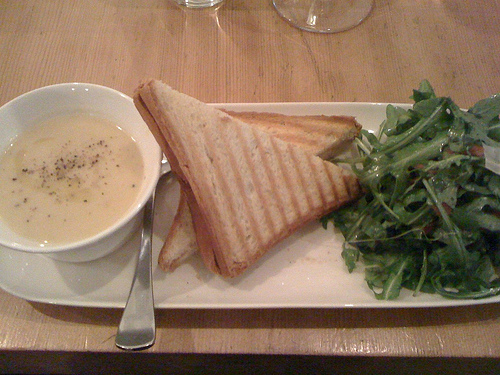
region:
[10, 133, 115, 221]
sprinkled black pepper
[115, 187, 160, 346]
handle of silver piece of silverware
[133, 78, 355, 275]
toasted half of sandwich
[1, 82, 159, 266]
cream soup in white bowl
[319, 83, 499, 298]
green leafy salad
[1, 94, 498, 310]
narrow white ceramic plate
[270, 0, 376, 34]
base of a clear glass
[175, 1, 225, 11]
base of a clear glass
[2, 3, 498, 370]
smooth flat wooden table top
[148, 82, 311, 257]
white and tan pieces of bread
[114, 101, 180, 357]
silver spoon on plate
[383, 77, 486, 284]
bunch of green lettuce leaves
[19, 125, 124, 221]
bowl of clam chowder soup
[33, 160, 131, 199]
black pepper on top of soup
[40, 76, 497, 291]
large white rounded plate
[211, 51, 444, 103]
light wood grain table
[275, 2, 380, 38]
bottom part of wine glass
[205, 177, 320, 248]
toast line marks on bread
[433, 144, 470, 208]
hidden tomatoes under leaves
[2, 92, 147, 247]
Bowl of dipping sauce.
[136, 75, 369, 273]
Sandwich halves on a plate.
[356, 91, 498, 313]
Leafy green vegetables on white plate.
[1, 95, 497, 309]
White platter with food.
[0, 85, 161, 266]
White bowl on left side of plate.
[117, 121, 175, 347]
Piece of silverware.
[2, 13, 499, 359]
Plate of food sitting on a wood table.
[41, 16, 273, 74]
Wood grain design on table.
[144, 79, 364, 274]
Toasted bread.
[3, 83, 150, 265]
Yellow cream sauce in a white bowl.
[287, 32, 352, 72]
small black line on surface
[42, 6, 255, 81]
clear pink surface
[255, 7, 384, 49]
rim of clear glass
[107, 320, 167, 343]
edge of broad silver spoon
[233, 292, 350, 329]
edge of white dinner plate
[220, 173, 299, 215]
lines in white toast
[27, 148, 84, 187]
black pepper in bowl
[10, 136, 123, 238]
creamy white soup in bowl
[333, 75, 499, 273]
selection of green on plate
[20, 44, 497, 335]
large white plate with food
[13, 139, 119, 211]
flecks of black pepper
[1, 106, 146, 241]
yellow dipping sauce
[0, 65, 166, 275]
white bowl holding a yellow sauce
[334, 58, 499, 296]
oil covered green arugula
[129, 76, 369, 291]
two triangles of grilled cheese sandwhich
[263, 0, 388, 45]
clear base of a glass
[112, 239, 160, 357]
silver metal handle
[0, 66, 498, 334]
oval shaped white dinner plate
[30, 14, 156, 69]
brown wooden table top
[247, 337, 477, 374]
brown edge of a table top